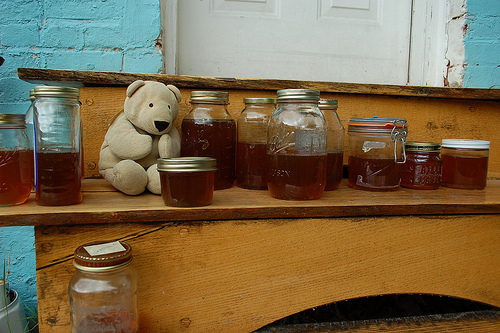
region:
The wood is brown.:
[207, 232, 395, 277]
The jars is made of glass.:
[61, 235, 159, 332]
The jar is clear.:
[53, 236, 156, 328]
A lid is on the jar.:
[56, 231, 139, 275]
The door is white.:
[158, 2, 445, 99]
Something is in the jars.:
[186, 88, 433, 193]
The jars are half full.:
[184, 83, 469, 203]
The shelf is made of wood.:
[201, 221, 443, 272]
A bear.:
[71, 71, 185, 204]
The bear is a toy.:
[83, 59, 225, 229]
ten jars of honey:
[0, 87, 497, 202]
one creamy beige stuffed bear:
[94, 79, 189, 194]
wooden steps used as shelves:
[1, 55, 499, 332]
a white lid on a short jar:
[442, 127, 491, 155]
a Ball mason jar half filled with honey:
[265, 80, 328, 201]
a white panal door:
[156, 0, 459, 84]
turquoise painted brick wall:
[7, 2, 156, 72]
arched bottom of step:
[219, 285, 499, 332]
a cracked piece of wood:
[34, 217, 189, 279]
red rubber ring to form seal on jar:
[348, 112, 408, 137]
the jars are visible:
[257, 52, 493, 293]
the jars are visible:
[190, 49, 390, 259]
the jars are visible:
[222, 126, 364, 303]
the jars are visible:
[187, 83, 321, 221]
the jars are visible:
[172, 110, 277, 203]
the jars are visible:
[186, 32, 301, 142]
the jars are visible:
[246, 84, 371, 239]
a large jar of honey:
[28, 82, 85, 205]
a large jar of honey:
[154, 149, 216, 210]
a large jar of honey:
[0, 110, 30, 202]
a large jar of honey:
[176, 87, 236, 187]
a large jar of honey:
[233, 89, 273, 189]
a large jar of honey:
[266, 89, 324, 199]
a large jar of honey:
[317, 99, 344, 191]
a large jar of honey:
[348, 111, 403, 188]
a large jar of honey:
[400, 139, 442, 190]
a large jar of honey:
[439, 139, 489, 191]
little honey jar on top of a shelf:
[158, 153, 225, 204]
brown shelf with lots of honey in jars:
[0, 96, 499, 236]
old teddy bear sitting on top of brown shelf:
[97, 78, 231, 205]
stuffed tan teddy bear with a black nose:
[101, 75, 186, 190]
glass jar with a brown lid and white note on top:
[65, 229, 147, 325]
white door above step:
[180, 4, 395, 76]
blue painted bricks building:
[2, 0, 159, 80]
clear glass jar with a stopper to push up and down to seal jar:
[346, 104, 411, 192]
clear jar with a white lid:
[443, 136, 493, 190]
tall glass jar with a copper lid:
[31, 78, 81, 205]